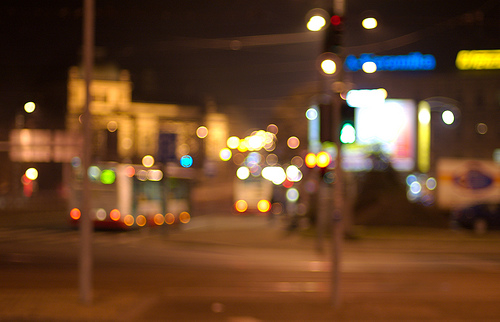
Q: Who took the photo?
A: The photographer.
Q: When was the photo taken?
A: Night time.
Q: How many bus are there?
A: Two.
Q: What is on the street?
A: The vehicles.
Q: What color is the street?
A: Black.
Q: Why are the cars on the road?
A: Driving.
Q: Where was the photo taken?
A: On the street at night.